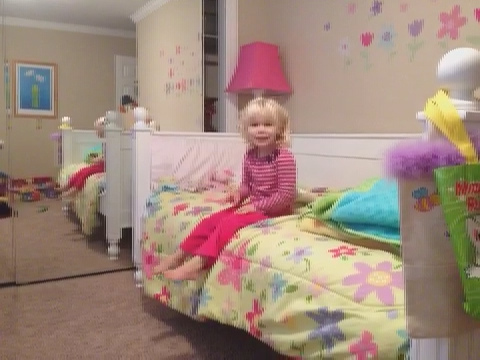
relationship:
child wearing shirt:
[142, 90, 312, 284] [227, 142, 300, 222]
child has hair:
[142, 90, 312, 284] [230, 92, 305, 154]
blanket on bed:
[135, 168, 416, 358] [124, 41, 478, 358]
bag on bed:
[423, 153, 479, 325] [124, 41, 478, 358]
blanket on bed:
[294, 176, 400, 257] [124, 41, 478, 358]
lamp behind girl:
[218, 48, 300, 125] [148, 97, 330, 279]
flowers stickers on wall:
[322, 0, 479, 69] [337, 116, 377, 166]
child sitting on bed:
[150, 96, 295, 282] [110, 106, 453, 353]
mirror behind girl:
[9, 21, 207, 288] [160, 90, 335, 288]